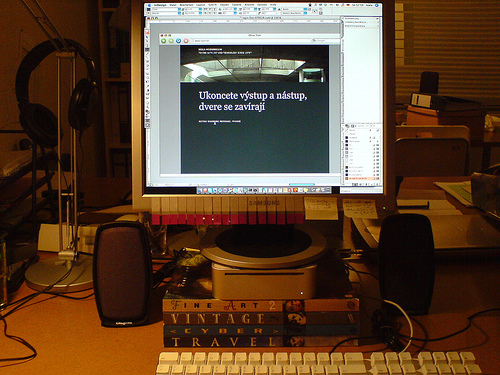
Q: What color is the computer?
A: Silver.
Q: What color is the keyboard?
A: White.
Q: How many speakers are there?
A: Two.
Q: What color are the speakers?
A: Black.